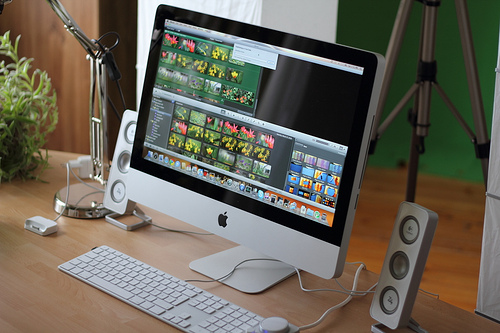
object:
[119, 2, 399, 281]
computer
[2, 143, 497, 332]
desk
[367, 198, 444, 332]
speaker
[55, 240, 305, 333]
keyboard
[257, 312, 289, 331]
knob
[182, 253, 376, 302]
wire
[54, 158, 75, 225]
wire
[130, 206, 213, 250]
wire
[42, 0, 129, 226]
desk lamp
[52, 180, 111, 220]
base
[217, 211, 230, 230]
logo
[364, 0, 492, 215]
tripod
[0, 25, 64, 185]
plant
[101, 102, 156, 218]
speaker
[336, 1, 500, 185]
wall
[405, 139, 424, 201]
base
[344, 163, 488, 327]
floor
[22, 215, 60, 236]
charger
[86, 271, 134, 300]
spacebar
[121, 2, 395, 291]
monitor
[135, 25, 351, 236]
website page